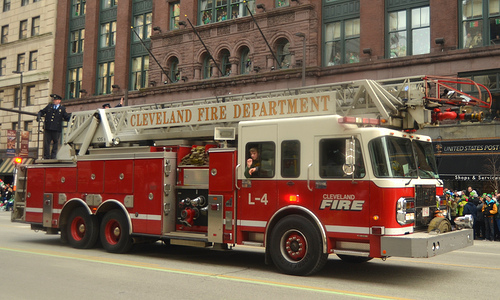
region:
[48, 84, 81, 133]
Hat on man's head.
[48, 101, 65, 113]
Man wearing blue shirt.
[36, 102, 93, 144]
Man wearing dark jacket.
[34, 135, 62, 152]
Man wearing dark pants.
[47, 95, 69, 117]
Tie around man's neck.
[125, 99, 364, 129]
Yellow writing on fire truck.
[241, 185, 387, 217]
White writing on side of truck.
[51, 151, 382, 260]
Truck is mostly red in color.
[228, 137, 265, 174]
Person waving out of window.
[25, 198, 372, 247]
White stripe on side of truck.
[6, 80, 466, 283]
Fire Truck on the street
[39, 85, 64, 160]
Man riding on a fire truck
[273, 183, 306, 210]
red light on a fire truck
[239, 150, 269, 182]
person looking out of window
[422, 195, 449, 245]
fire truck with a hose on it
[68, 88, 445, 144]
Ladder on top of a fire truck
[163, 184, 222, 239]
gauges on a fire truck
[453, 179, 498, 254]
Crowd watching a fire truck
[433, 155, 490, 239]
Crowd watching a firetruck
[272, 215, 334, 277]
Fire truck with red rim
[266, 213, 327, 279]
A black round tire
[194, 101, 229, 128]
The word "FIRE" on a sign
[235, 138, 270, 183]
Man inside the firetruck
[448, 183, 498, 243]
People standing on a sidewalk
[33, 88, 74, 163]
Man standing on firetruck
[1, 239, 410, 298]
Lines on the street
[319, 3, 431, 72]
Two windows on a building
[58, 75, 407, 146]
A ladder on top of firetruck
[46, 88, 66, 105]
Hat on man's head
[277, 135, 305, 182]
A window on the firetruck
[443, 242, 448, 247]
part of a wall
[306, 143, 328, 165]
part of a wiondow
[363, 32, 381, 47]
part of a building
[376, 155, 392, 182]
edge of a truck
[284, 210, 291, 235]
part of a wheel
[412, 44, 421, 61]
part of a window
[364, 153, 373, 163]
part of a truck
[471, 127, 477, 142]
part of a wall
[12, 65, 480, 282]
A red firetruck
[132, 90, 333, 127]
The ladder reads "Cleveland fire department"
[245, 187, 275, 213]
Fire truck number L-4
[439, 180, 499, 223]
People watching the firetruck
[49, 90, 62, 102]
The fireman has a black hat.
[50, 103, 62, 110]
The fireman wears a blue shirt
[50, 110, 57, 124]
Three buttons visible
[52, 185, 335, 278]
The rims of the tires are red.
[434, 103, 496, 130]
A fire hose at the end of the ladder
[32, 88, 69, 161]
A fireman standing at the back of fire truck.